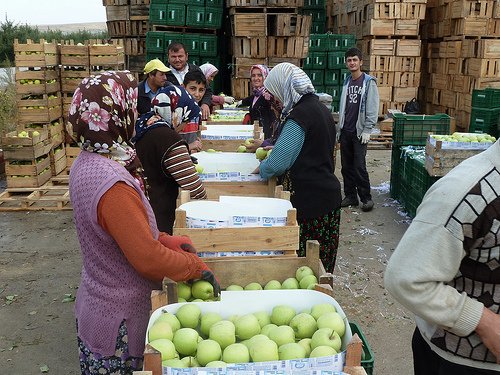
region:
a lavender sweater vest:
[68, 153, 159, 356]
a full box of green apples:
[157, 298, 349, 368]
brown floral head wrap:
[71, 70, 149, 195]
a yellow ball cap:
[142, 58, 170, 73]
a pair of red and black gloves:
[159, 233, 221, 295]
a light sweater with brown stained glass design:
[377, 142, 499, 367]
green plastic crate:
[390, 111, 449, 148]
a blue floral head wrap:
[136, 88, 198, 138]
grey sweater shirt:
[337, 72, 379, 137]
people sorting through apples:
[65, 42, 497, 373]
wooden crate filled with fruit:
[152, 304, 392, 374]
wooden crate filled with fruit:
[187, 148, 289, 197]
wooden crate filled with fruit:
[16, 67, 53, 96]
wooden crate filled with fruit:
[19, 97, 55, 122]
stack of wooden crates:
[443, 20, 473, 95]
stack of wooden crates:
[371, 20, 396, 47]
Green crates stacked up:
[141, 1, 498, 220]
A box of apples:
[137, 266, 356, 373]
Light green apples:
[154, 251, 342, 373]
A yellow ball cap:
[139, 56, 176, 76]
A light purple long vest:
[49, 150, 166, 358]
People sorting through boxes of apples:
[61, 36, 377, 370]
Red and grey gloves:
[156, 222, 223, 295]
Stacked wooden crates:
[4, 1, 495, 225]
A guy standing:
[324, 44, 389, 217]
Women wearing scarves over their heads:
[60, 56, 347, 353]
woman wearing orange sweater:
[118, 213, 133, 233]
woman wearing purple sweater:
[78, 234, 99, 264]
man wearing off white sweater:
[411, 248, 443, 271]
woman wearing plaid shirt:
[177, 155, 189, 175]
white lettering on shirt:
[349, 84, 361, 102]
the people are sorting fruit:
[62, 21, 415, 369]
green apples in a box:
[142, 295, 371, 369]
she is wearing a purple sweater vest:
[58, 139, 240, 366]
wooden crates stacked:
[8, 33, 158, 247]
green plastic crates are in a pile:
[303, 5, 360, 92]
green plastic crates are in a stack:
[308, 15, 364, 110]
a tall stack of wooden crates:
[354, 3, 426, 139]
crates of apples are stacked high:
[9, 35, 109, 206]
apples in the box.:
[154, 290, 353, 364]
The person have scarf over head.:
[68, 66, 138, 168]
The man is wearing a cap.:
[135, 60, 177, 80]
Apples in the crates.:
[18, 53, 54, 123]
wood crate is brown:
[14, 39, 57, 66]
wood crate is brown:
[14, 67, 61, 97]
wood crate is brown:
[17, 94, 63, 124]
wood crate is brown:
[6, 126, 51, 161]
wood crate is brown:
[6, 157, 49, 187]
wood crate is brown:
[59, 40, 91, 65]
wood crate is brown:
[89, 39, 124, 66]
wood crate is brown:
[59, 68, 88, 93]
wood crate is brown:
[60, 93, 78, 117]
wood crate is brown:
[66, 144, 83, 170]